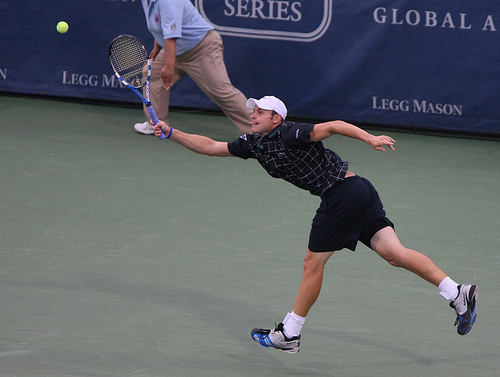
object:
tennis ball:
[57, 21, 69, 35]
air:
[12, 38, 111, 149]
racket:
[105, 33, 167, 140]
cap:
[244, 94, 291, 116]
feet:
[246, 317, 301, 356]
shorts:
[308, 171, 399, 256]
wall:
[195, 0, 500, 136]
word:
[371, 8, 475, 35]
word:
[221, 0, 306, 24]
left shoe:
[247, 326, 304, 356]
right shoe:
[450, 282, 480, 337]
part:
[63, 251, 104, 300]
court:
[0, 92, 500, 376]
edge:
[290, 309, 312, 325]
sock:
[283, 313, 304, 342]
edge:
[279, 329, 301, 341]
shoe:
[245, 327, 302, 356]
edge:
[306, 242, 366, 254]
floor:
[0, 95, 500, 377]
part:
[305, 260, 309, 263]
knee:
[302, 251, 328, 275]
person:
[136, 0, 256, 142]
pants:
[143, 33, 254, 132]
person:
[151, 96, 485, 358]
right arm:
[145, 120, 258, 163]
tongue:
[249, 120, 259, 126]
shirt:
[140, 0, 212, 50]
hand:
[146, 121, 177, 143]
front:
[152, 106, 185, 146]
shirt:
[224, 122, 353, 197]